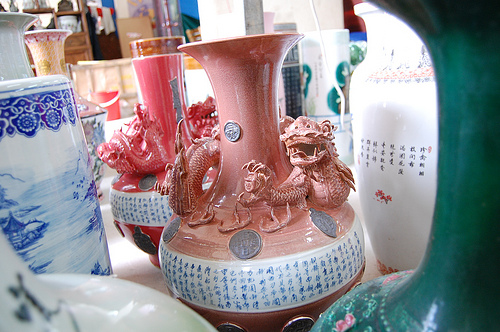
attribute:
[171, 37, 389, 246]
ceramic vase — tall, green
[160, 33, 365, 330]
vase — red, brown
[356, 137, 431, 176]
writing — Asian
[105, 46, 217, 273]
vase — red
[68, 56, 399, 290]
vase — white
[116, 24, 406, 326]
vase — brown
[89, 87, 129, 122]
bucket — red, small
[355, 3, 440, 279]
vase — dark, green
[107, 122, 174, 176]
dragon — red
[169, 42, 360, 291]
vase — brown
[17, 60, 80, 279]
vase — blue, white, decorative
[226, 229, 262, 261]
coin — silver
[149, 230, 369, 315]
lettering — black